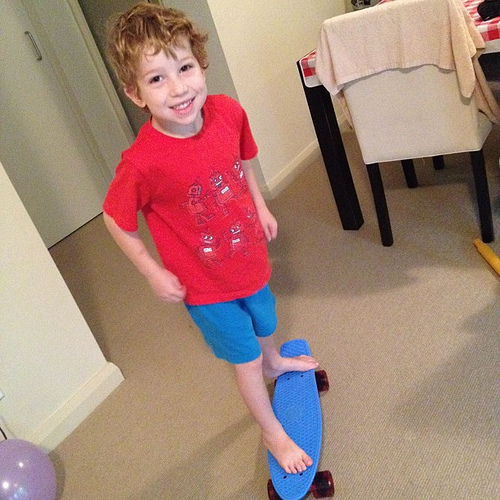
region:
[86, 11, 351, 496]
a little boy standing on blue skateboard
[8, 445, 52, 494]
a lavender balloon on the floor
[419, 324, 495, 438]
beige carpet covering the floor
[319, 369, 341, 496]
red wheels on the skateboard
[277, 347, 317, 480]
two little bare feet on the skateboard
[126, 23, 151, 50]
shaggy brown hair on a head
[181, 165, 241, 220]
robot print on a red t-shirt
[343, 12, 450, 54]
a beige towel on the back of a chair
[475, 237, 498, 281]
a yellow toy on the floor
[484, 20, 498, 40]
a red and white checkered table cloth on the table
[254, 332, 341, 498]
blue plastic skateboard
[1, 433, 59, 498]
pink colored balloon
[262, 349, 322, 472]
boy's bare feet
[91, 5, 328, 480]
boy standing on a skateboard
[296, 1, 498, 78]
red and white checked table cloth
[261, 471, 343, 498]
front wheels on a skateboard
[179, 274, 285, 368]
boy's blue shorts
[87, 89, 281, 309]
boy's red tee shirt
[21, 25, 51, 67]
handle on a white door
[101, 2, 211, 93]
unbrushed hair of a boy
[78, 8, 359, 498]
boy standing on skateboard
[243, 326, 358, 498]
blue skate board with red wheels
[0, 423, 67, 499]
childs pink ball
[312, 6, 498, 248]
white chair with brown legs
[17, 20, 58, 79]
metal door handle to door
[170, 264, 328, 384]
boys bright blue shorts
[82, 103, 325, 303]
boys red shirt with robots on it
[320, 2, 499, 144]
cream colored towel drape over chair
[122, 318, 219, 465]
beige carpet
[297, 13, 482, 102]
red and white checkered table cloth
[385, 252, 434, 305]
part of the floor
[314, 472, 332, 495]
wheel of a skateboard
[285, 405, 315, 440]
part of a skateboard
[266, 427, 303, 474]
part of a leg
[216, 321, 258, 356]
part of a short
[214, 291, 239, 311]
edge of a shirt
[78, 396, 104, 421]
edge of a wall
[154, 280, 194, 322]
part of a right hand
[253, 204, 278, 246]
part of the left hand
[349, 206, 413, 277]
part of some stands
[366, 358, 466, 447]
this is the floor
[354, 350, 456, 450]
the floor has a carpet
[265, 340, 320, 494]
this is a skateboard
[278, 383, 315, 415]
the skateboard is blue in color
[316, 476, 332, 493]
the wheels are red in color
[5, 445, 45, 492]
this is a balloon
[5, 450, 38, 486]
the balloon is purple in color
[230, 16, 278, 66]
this is the wall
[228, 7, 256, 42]
the wall is white in color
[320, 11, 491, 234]
this is a chair